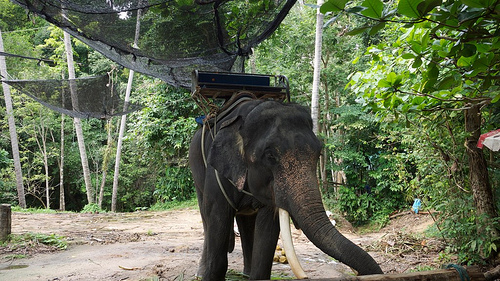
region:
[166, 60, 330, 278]
A grey elephant in the foreground.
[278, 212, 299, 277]
white tusks.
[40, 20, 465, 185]
A green forest in the background.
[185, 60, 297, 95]
A seat for passengers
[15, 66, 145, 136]
Black mosquito nets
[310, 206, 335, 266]
A elephants long trunk.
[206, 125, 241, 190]
large grey elephant ear.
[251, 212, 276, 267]
Elephant's cylindrical leg.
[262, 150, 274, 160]
Small eye of an elephant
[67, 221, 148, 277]
Brown, dusty dirty ground.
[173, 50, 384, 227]
the elephant is carrying chair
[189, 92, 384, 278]
elephant facing camera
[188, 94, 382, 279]
elephant that is gray in color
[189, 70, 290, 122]
seat on elephant's back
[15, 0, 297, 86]
hamper hanging from tree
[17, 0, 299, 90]
black hamper from tree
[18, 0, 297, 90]
black, mesh hamper over elephant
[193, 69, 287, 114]
seat on elephant's back is blue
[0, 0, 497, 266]
trees are green in color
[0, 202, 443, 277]
ground is tan in color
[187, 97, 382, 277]
elephant is large in size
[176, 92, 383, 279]
A gray elephant in the forest.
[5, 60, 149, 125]
A hanging net on a tree.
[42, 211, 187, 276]
A path in the forest.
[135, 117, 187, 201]
some trees in the forest.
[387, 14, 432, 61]
Green leaves on a tree.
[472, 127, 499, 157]
A red piece of cloth.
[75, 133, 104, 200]
A pole of a tree.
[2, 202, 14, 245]
A tree stump.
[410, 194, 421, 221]
A blue piece of clothe.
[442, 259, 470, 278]
A blue ribbon.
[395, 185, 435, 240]
the plastic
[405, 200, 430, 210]
the plastic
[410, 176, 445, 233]
the plastic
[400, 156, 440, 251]
the plastic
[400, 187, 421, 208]
the plastic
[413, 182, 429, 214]
the plastic